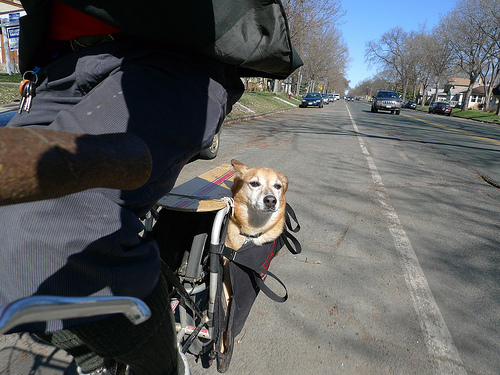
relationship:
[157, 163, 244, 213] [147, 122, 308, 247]
stripe on skateboard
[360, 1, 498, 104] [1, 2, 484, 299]
tree in neighborhood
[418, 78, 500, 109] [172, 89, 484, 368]
house along street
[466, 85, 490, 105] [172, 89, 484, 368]
house along street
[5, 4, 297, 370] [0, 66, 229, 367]
man wearing pants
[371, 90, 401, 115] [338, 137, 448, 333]
car driving down street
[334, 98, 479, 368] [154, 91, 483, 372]
line dividing road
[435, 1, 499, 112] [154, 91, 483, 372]
tree along road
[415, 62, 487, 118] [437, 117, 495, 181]
buildings beside road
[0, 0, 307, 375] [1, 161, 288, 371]
man riding bicycle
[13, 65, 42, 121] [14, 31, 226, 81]
keys hanging from belt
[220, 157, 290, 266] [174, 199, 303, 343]
dog in bag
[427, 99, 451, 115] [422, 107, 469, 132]
car on street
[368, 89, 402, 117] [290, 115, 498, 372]
car on street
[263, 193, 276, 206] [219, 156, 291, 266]
nose on dog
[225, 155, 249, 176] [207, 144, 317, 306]
ear on dog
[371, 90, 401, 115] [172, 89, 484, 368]
car on street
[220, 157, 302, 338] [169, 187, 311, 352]
dog riding in carrier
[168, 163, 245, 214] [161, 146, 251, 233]
stripe on board